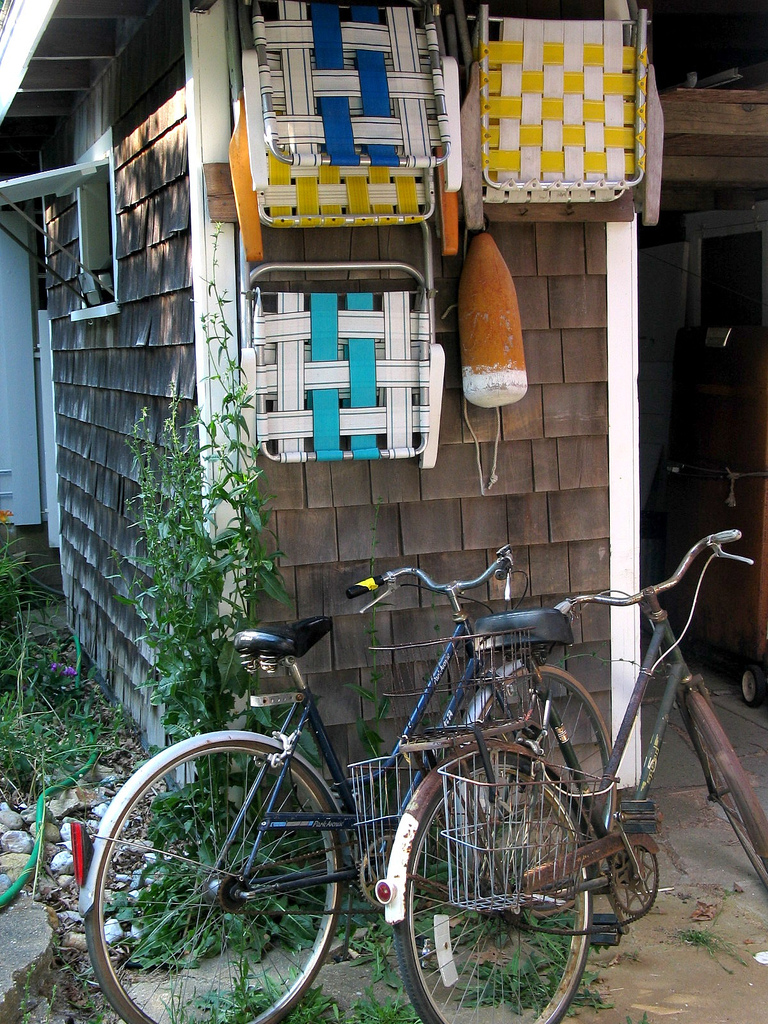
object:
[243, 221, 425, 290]
wall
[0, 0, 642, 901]
building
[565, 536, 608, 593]
siding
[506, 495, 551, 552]
siding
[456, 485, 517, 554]
siding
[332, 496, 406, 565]
siding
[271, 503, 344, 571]
siding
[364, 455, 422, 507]
siding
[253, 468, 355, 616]
wall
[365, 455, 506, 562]
wall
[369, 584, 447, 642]
wall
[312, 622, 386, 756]
wall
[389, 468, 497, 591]
wall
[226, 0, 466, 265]
chair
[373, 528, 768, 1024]
bicycle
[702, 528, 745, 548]
handle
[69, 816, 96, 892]
light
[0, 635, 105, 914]
hose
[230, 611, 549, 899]
racks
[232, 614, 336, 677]
seats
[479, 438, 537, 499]
shingle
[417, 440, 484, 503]
shingle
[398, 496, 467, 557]
shingle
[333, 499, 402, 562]
shingle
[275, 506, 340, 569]
shingle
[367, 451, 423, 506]
shingle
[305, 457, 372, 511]
shingle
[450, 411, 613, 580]
wall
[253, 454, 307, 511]
shingle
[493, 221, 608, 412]
wall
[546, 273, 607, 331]
shingle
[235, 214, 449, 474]
chair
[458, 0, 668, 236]
chair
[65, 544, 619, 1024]
bike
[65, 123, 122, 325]
window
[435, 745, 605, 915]
basket